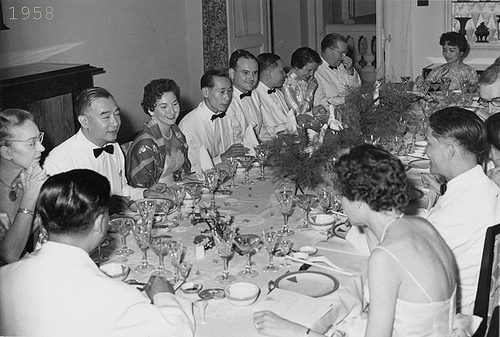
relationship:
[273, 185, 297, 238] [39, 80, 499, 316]
wine glass on top of table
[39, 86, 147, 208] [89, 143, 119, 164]
person wearing tie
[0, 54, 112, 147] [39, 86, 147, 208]
desk behind person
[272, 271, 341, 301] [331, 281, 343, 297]
plate has edge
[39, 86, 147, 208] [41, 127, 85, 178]
person has shoulder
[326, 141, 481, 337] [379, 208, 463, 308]
person has back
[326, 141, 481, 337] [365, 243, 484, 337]
person wearing dress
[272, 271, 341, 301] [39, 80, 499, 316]
plate on top of table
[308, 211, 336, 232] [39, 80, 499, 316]
bowl on top of table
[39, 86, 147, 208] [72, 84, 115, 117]
person has short haircut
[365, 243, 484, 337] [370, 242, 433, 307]
dress has string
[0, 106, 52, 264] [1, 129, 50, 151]
woman wearing glasses